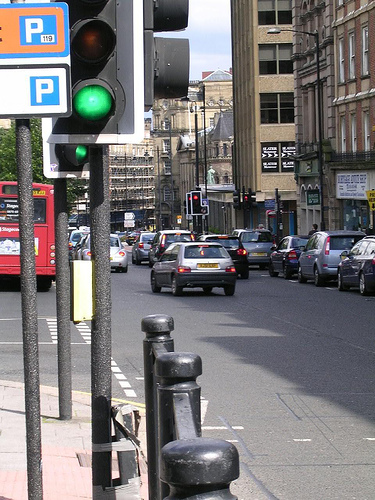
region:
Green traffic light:
[71, 82, 121, 124]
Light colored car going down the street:
[148, 241, 238, 295]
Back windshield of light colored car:
[184, 244, 231, 260]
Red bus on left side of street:
[1, 180, 57, 292]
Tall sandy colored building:
[230, 0, 297, 202]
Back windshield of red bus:
[0, 197, 47, 223]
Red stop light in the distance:
[187, 191, 210, 216]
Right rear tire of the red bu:
[30, 272, 54, 293]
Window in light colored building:
[254, 88, 300, 127]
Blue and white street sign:
[27, 72, 64, 109]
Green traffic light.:
[68, 1, 136, 140]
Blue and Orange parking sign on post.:
[36, 8, 63, 53]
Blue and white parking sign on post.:
[30, 75, 60, 103]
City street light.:
[258, 22, 325, 47]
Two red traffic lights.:
[184, 189, 203, 215]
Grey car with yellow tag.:
[155, 242, 236, 289]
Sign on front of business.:
[338, 172, 368, 198]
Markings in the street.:
[35, 307, 139, 395]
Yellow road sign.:
[366, 187, 374, 213]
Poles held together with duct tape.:
[89, 392, 145, 498]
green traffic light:
[73, 84, 115, 124]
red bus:
[0, 180, 54, 276]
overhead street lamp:
[265, 25, 325, 94]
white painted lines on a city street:
[113, 364, 137, 398]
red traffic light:
[192, 194, 198, 199]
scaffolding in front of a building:
[113, 155, 151, 209]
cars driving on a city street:
[130, 230, 248, 292]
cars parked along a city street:
[276, 233, 371, 295]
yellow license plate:
[193, 261, 223, 270]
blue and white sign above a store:
[334, 173, 365, 197]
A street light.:
[269, 26, 344, 246]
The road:
[0, 211, 373, 497]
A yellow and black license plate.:
[194, 263, 219, 269]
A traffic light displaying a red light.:
[188, 190, 205, 214]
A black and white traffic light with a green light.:
[48, 1, 142, 142]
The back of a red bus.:
[0, 177, 58, 292]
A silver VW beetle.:
[78, 233, 128, 271]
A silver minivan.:
[296, 228, 365, 289]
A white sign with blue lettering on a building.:
[332, 169, 372, 198]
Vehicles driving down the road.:
[69, 222, 373, 312]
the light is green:
[60, 80, 147, 152]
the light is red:
[179, 184, 209, 205]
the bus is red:
[1, 171, 74, 287]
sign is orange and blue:
[0, 0, 87, 63]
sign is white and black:
[0, 67, 74, 117]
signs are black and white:
[260, 133, 295, 174]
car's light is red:
[165, 257, 249, 282]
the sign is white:
[320, 158, 373, 207]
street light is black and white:
[176, 179, 212, 220]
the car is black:
[209, 226, 252, 267]